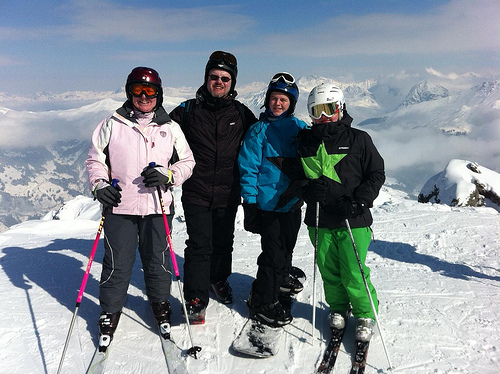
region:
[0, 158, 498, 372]
the top of a ski slope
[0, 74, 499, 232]
a large mountainous landscape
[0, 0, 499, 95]
an area of blue cloudy sky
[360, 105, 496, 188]
a group of clouds in the mountains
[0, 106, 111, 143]
a cloud in the mountains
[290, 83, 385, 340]
a person skiing on the slope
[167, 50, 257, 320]
a man standing on the slope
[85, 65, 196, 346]
a woman skiing on the slope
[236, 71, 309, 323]
a girl snowboarding on the slope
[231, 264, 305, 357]
the girl's snowboard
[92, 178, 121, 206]
a woman's right glove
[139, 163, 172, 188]
a woman's left glove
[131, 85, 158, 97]
a woman's ski goggles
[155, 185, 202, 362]
a woman's ski pole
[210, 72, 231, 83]
a man's sunglasses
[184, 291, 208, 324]
a man's right boot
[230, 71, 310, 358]
a boy on a snowboard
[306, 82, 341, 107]
a girl's ski helmet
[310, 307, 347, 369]
a girl's right ski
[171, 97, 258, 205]
a man's ski jacket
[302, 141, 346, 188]
A green star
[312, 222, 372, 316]
Bright green pants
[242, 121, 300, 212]
Blue jacket with black star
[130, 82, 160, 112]
orange goggles on face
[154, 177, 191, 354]
Pink ski on the right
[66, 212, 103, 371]
Pink ski on the left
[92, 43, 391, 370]
Four skiers on a mountain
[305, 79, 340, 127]
White helment and yellow goggles on face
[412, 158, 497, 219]
Small rock on the right covered in snow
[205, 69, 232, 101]
Sunglasses on mans face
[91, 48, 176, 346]
person standing on ski slope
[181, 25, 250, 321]
person standing on ski slope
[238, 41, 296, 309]
person standing on ski slope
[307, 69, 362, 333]
person standing on ski slope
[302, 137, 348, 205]
green star on truck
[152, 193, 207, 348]
ski pole in skier's hand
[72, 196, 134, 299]
ski pole in skier's hand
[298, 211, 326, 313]
ski pole in skier's hand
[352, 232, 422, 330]
ski pole in skier's hand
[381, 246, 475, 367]
white thick snow on mountain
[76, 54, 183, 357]
skier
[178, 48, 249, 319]
man skier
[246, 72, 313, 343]
skier on hill side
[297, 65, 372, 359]
skier on hill side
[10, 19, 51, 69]
white clouds in blue sky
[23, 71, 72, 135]
white clouds in blue sky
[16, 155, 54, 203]
white clouds in blue sky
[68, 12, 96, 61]
white clouds in blue sky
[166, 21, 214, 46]
white clouds in blue sky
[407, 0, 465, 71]
white clouds in blue sky